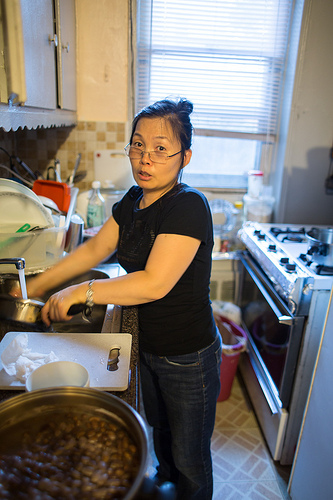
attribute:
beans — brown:
[48, 416, 107, 459]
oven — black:
[235, 220, 329, 412]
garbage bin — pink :
[211, 308, 246, 403]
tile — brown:
[0, 123, 126, 187]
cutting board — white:
[2, 331, 132, 391]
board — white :
[6, 324, 133, 387]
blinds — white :
[133, 0, 308, 142]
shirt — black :
[113, 187, 220, 353]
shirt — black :
[108, 181, 216, 357]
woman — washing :
[125, 96, 196, 200]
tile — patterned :
[230, 465, 258, 488]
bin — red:
[213, 307, 248, 402]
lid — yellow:
[233, 200, 244, 209]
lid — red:
[247, 169, 264, 178]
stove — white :
[234, 221, 323, 463]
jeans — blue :
[135, 329, 222, 498]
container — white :
[25, 359, 89, 391]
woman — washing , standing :
[18, 99, 225, 499]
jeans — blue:
[133, 339, 226, 498]